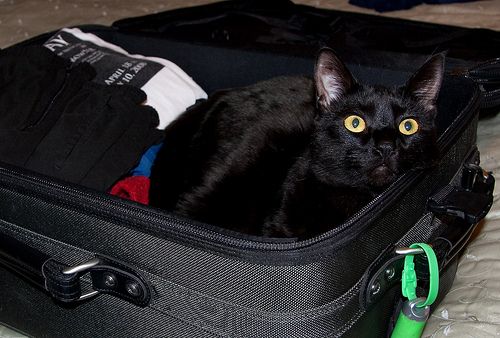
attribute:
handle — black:
[5, 216, 158, 315]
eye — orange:
[395, 117, 417, 137]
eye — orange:
[343, 114, 366, 135]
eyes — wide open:
[334, 111, 424, 140]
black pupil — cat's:
[352, 118, 359, 127]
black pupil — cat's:
[404, 120, 411, 130]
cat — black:
[150, 45, 446, 241]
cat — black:
[144, 54, 493, 234]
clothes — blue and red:
[46, 74, 164, 191]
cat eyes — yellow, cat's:
[344, 115, 418, 135]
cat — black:
[119, 54, 450, 246]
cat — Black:
[159, 73, 436, 201]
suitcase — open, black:
[12, 5, 483, 323]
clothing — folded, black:
[18, 29, 189, 184]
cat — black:
[161, 50, 453, 214]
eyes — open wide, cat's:
[340, 111, 419, 136]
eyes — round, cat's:
[338, 114, 420, 134]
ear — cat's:
[399, 44, 445, 110]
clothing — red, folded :
[109, 173, 150, 204]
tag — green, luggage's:
[394, 236, 439, 309]